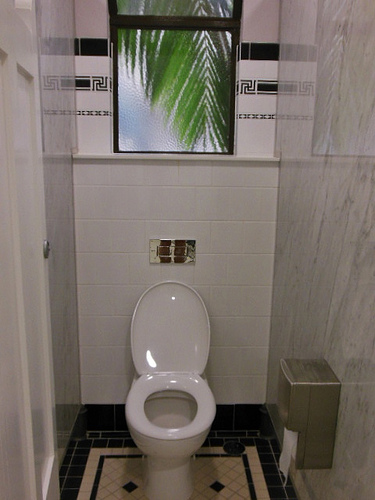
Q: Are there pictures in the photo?
A: No, there are no pictures.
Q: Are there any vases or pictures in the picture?
A: No, there are no pictures or vases.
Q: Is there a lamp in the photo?
A: No, there are no lamps.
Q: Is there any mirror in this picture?
A: No, there are no mirrors.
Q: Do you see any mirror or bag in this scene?
A: No, there are no mirrors or bags.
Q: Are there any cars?
A: No, there are no cars.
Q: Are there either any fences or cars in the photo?
A: No, there are no cars or fences.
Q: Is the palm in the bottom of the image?
A: No, the palm is in the top of the image.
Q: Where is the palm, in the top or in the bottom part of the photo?
A: The palm is in the top of the image.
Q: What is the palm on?
A: The palm is on the wall.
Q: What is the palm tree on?
A: The palm is on the wall.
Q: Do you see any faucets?
A: No, there are no faucets.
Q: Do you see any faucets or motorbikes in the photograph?
A: No, there are no faucets or motorbikes.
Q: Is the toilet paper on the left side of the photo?
A: No, the toilet paper is on the right of the image.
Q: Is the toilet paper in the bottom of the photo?
A: Yes, the toilet paper is in the bottom of the image.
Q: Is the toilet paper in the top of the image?
A: No, the toilet paper is in the bottom of the image.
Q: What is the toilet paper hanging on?
A: The toilet paper is hanging on the wall.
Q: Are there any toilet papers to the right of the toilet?
A: Yes, there is a toilet paper to the right of the toilet.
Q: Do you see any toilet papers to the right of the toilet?
A: Yes, there is a toilet paper to the right of the toilet.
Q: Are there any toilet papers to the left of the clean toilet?
A: No, the toilet paper is to the right of the toilet.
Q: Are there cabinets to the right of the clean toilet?
A: No, there is a toilet paper to the right of the toilet.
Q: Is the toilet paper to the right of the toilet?
A: Yes, the toilet paper is to the right of the toilet.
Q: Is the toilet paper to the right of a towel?
A: No, the toilet paper is to the right of the toilet.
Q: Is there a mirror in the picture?
A: No, there are no mirrors.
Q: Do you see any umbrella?
A: No, there are no umbrellas.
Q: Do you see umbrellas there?
A: No, there are no umbrellas.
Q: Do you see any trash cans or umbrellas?
A: No, there are no umbrellas or trash cans.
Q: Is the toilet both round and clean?
A: Yes, the toilet is round and clean.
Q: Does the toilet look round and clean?
A: Yes, the toilet is round and clean.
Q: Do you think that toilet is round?
A: Yes, the toilet is round.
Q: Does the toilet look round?
A: Yes, the toilet is round.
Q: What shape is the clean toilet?
A: The toilet is round.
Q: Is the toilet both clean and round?
A: Yes, the toilet is clean and round.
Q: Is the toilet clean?
A: Yes, the toilet is clean.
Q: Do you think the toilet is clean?
A: Yes, the toilet is clean.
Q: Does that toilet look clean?
A: Yes, the toilet is clean.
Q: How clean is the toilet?
A: The toilet is clean.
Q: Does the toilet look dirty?
A: No, the toilet is clean.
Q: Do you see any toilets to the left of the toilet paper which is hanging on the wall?
A: Yes, there is a toilet to the left of the toilet paper.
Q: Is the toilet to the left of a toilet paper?
A: Yes, the toilet is to the left of a toilet paper.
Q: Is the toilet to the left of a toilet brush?
A: No, the toilet is to the left of a toilet paper.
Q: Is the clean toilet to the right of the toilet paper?
A: No, the toilet is to the left of the toilet paper.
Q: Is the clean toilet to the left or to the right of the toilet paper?
A: The toilet is to the left of the toilet paper.